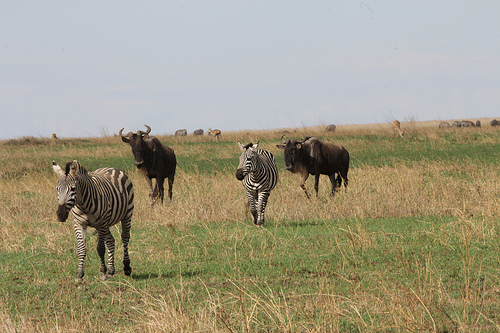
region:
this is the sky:
[220, 16, 393, 78]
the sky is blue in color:
[206, 44, 317, 74]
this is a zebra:
[228, 128, 277, 208]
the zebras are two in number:
[43, 148, 272, 266]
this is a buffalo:
[286, 133, 350, 195]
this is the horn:
[138, 125, 158, 141]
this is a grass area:
[384, 259, 457, 326]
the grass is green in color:
[316, 268, 388, 308]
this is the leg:
[255, 188, 276, 230]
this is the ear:
[63, 158, 84, 172]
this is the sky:
[200, 17, 357, 91]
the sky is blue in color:
[68, 28, 224, 83]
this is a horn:
[136, 125, 155, 132]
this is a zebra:
[235, 136, 277, 226]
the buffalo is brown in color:
[311, 144, 338, 166]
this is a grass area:
[331, 223, 406, 293]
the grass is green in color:
[295, 253, 360, 292]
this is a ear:
[68, 150, 85, 167]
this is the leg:
[91, 226, 111, 271]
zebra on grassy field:
[42, 156, 152, 277]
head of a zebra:
[46, 163, 86, 216]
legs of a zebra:
[71, 223, 139, 271]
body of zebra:
[91, 167, 143, 220]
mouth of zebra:
[52, 195, 74, 227]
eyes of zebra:
[69, 183, 80, 193]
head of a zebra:
[233, 135, 260, 179]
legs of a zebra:
[245, 191, 278, 218]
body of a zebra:
[261, 150, 283, 180]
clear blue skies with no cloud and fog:
[149, 18, 358, 75]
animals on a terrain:
[34, 82, 423, 304]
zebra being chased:
[31, 73, 207, 308]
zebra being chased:
[231, 72, 418, 244]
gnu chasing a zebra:
[36, 73, 209, 284]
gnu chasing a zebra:
[223, 89, 390, 259]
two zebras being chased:
[24, 83, 421, 312]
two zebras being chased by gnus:
[23, 52, 464, 297]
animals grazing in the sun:
[40, 101, 499, 168]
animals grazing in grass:
[26, 20, 471, 184]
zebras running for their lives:
[35, 89, 335, 324]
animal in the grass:
[114, 125, 193, 203]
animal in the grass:
[43, 155, 141, 282]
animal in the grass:
[231, 130, 282, 227]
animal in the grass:
[277, 133, 353, 201]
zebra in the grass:
[45, 158, 140, 282]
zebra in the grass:
[230, 134, 280, 227]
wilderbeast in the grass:
[120, 121, 185, 204]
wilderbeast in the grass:
[276, 135, 352, 197]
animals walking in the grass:
[45, 123, 360, 283]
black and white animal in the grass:
[237, 142, 279, 224]